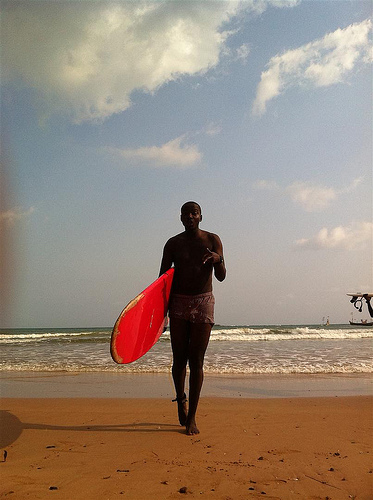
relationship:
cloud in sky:
[1, 22, 371, 253] [138, 90, 226, 136]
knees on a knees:
[166, 349, 203, 372] [173, 354, 204, 373]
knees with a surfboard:
[173, 354, 204, 373] [87, 267, 212, 363]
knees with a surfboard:
[173, 354, 204, 373] [101, 270, 172, 364]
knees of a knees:
[173, 354, 204, 373] [173, 354, 204, 373]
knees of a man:
[173, 354, 204, 373] [158, 198, 226, 435]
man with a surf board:
[158, 198, 226, 435] [109, 267, 174, 364]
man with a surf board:
[158, 198, 226, 435] [111, 264, 178, 370]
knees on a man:
[173, 354, 204, 373] [158, 198, 226, 435]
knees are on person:
[173, 354, 204, 373] [155, 191, 247, 424]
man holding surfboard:
[158, 198, 226, 435] [108, 266, 176, 364]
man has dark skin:
[158, 198, 226, 435] [156, 199, 227, 435]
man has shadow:
[158, 198, 226, 435] [0, 416, 190, 433]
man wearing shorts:
[135, 189, 236, 426] [134, 279, 237, 341]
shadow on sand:
[2, 408, 183, 453] [0, 394, 372, 498]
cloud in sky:
[291, 216, 371, 252] [0, 2, 370, 329]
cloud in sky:
[1, 22, 371, 253] [0, 2, 370, 329]